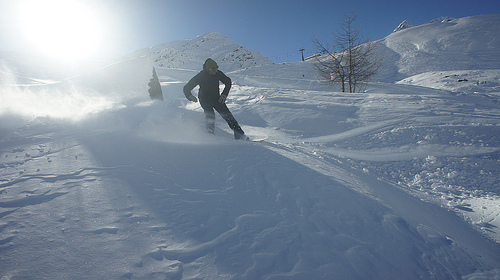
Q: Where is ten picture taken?
A: A ski slope.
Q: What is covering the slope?
A: Snow.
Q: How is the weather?
A: Clear and sunny.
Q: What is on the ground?
A: Snow.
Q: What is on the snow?
A: Skier.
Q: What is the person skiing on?
A: Snow.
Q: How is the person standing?
A: Leaning on skies.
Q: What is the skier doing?
A: Skiing downhill.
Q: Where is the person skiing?
A: On the mountain.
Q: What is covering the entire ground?
A: Snow.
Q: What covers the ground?
A: Lots of snow.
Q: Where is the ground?
A: Under the snow.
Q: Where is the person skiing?
A: In the snow.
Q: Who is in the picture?
A: A person.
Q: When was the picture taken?
A: During the day.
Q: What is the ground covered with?
A: Snow.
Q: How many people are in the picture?
A: No one.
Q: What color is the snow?
A: White.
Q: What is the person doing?
A: Skiing.